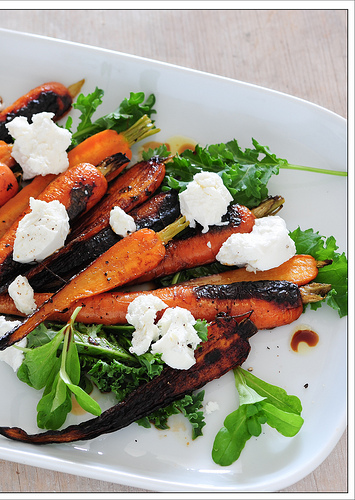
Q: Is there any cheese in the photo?
A: Yes, there is cheese.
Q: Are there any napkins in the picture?
A: No, there are no napkins.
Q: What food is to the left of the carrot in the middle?
A: The food is cheese.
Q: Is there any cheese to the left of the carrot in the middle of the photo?
A: Yes, there is cheese to the left of the carrot.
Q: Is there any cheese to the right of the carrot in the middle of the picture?
A: No, the cheese is to the left of the carrot.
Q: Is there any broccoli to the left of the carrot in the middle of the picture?
A: No, there is cheese to the left of the carrot.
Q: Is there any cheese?
A: Yes, there is cheese.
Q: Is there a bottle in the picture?
A: No, there are no bottles.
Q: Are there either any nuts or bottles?
A: No, there are no bottles or nuts.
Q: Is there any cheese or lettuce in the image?
A: Yes, there is cheese.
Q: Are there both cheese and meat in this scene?
A: No, there is cheese but no meat.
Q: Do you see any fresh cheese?
A: Yes, there is fresh cheese.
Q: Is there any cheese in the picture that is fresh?
A: Yes, there is cheese that is fresh.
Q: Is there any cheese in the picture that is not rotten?
A: Yes, there is fresh cheese.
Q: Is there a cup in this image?
A: No, there are no cups.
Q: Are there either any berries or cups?
A: No, there are no cups or berries.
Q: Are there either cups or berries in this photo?
A: No, there are no cups or berries.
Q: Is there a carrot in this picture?
A: Yes, there is a carrot.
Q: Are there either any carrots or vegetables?
A: Yes, there is a carrot.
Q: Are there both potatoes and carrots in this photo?
A: No, there is a carrot but no potatoes.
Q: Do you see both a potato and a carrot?
A: No, there is a carrot but no potatoes.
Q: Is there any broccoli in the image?
A: No, there is no broccoli.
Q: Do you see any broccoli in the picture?
A: No, there is no broccoli.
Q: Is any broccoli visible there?
A: No, there is no broccoli.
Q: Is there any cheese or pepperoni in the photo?
A: Yes, there is cheese.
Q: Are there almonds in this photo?
A: No, there are no almonds.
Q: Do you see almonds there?
A: No, there are no almonds.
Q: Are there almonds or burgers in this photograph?
A: No, there are no almonds or burgers.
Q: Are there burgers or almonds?
A: No, there are no almonds or burgers.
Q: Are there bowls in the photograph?
A: No, there are no bowls.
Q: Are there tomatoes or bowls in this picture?
A: No, there are no bowls or tomatoes.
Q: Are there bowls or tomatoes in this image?
A: No, there are no bowls or tomatoes.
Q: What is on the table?
A: The herb is on the table.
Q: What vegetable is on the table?
A: The vegetable is a herb.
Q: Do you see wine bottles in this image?
A: No, there are no wine bottles.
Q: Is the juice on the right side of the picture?
A: Yes, the juice is on the right of the image.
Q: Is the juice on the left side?
A: No, the juice is on the right of the image.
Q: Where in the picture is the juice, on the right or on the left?
A: The juice is on the right of the image.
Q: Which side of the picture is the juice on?
A: The juice is on the right of the image.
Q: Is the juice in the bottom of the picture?
A: Yes, the juice is in the bottom of the image.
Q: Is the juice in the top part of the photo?
A: No, the juice is in the bottom of the image.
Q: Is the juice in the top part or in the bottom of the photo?
A: The juice is in the bottom of the image.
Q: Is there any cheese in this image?
A: Yes, there is cheese.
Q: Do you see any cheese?
A: Yes, there is cheese.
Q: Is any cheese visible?
A: Yes, there is cheese.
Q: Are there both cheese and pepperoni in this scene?
A: No, there is cheese but no pepperoni.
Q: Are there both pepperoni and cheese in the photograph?
A: No, there is cheese but no pepperoni.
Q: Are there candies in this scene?
A: No, there are no candies.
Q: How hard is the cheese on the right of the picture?
A: The cheese is soft.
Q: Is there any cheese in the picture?
A: Yes, there is cheese.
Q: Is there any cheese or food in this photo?
A: Yes, there is cheese.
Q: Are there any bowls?
A: No, there are no bowls.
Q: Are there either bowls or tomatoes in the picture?
A: No, there are no bowls or tomatoes.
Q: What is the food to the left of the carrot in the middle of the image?
A: The food is cheese.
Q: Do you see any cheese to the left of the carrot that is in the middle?
A: Yes, there is cheese to the left of the carrot.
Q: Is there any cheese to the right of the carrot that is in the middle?
A: No, the cheese is to the left of the carrot.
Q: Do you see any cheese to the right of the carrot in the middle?
A: No, the cheese is to the left of the carrot.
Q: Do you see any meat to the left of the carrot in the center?
A: No, there is cheese to the left of the carrot.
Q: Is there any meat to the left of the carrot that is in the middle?
A: No, there is cheese to the left of the carrot.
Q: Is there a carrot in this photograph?
A: Yes, there is a carrot.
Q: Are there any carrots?
A: Yes, there is a carrot.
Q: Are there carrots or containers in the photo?
A: Yes, there is a carrot.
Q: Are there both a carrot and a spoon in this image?
A: No, there is a carrot but no spoons.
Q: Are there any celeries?
A: No, there are no celeries.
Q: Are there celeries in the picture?
A: No, there are no celeries.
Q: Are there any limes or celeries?
A: No, there are no celeries or limes.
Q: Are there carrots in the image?
A: Yes, there is a carrot.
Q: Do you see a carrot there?
A: Yes, there is a carrot.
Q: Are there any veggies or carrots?
A: Yes, there is a carrot.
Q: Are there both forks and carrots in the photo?
A: No, there is a carrot but no forks.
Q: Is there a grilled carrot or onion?
A: Yes, there is a grilled carrot.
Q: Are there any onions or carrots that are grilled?
A: Yes, the carrot is grilled.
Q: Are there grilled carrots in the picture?
A: Yes, there is a grilled carrot.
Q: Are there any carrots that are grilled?
A: Yes, there is a carrot that is grilled.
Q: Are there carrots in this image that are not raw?
A: Yes, there is a grilled carrot.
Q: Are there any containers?
A: No, there are no containers.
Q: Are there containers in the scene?
A: No, there are no containers.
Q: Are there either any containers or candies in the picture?
A: No, there are no containers or candies.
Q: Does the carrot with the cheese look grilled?
A: Yes, the carrot is grilled.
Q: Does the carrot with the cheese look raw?
A: No, the carrot is grilled.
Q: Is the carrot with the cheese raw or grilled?
A: The carrot is grilled.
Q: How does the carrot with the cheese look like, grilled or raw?
A: The carrot is grilled.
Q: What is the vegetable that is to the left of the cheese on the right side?
A: The vegetable is a carrot.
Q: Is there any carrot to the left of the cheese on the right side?
A: Yes, there is a carrot to the left of the cheese.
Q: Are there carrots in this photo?
A: Yes, there is a carrot.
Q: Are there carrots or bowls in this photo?
A: Yes, there is a carrot.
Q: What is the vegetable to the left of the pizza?
A: The vegetable is a carrot.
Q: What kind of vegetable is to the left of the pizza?
A: The vegetable is a carrot.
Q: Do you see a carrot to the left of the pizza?
A: Yes, there is a carrot to the left of the pizza.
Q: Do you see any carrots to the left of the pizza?
A: Yes, there is a carrot to the left of the pizza.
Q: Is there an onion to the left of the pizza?
A: No, there is a carrot to the left of the pizza.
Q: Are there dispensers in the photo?
A: No, there are no dispensers.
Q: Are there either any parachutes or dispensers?
A: No, there are no dispensers or parachutes.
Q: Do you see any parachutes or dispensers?
A: No, there are no dispensers or parachutes.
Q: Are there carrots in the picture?
A: Yes, there are carrots.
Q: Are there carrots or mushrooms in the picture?
A: Yes, there are carrots.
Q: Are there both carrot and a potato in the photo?
A: No, there are carrots but no potatoes.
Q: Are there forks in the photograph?
A: No, there are no forks.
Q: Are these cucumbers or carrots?
A: These are carrots.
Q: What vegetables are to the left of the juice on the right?
A: The vegetables are carrots.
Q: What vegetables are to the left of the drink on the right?
A: The vegetables are carrots.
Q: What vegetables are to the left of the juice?
A: The vegetables are carrots.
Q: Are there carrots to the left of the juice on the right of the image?
A: Yes, there are carrots to the left of the juice.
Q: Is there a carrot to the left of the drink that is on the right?
A: Yes, there are carrots to the left of the juice.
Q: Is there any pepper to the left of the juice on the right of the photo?
A: No, there are carrots to the left of the juice.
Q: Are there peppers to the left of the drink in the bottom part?
A: No, there are carrots to the left of the juice.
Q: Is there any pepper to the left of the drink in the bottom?
A: No, there are carrots to the left of the juice.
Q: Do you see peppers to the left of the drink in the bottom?
A: No, there are carrots to the left of the juice.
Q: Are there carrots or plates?
A: Yes, there is a carrot.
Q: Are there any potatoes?
A: No, there are no potatoes.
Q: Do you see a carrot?
A: Yes, there is a carrot.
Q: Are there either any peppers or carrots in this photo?
A: Yes, there is a carrot.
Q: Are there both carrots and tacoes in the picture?
A: No, there is a carrot but no tacoes.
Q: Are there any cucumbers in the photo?
A: No, there are no cucumbers.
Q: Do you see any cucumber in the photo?
A: No, there are no cucumbers.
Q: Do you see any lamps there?
A: No, there are no lamps.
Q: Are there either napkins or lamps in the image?
A: No, there are no lamps or napkins.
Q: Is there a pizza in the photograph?
A: Yes, there is a pizza.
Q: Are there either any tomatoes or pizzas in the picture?
A: Yes, there is a pizza.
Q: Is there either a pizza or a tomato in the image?
A: Yes, there is a pizza.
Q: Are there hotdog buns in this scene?
A: No, there are no hotdog buns.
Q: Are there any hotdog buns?
A: No, there are no hotdog buns.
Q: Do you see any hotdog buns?
A: No, there are no hotdog buns.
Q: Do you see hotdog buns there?
A: No, there are no hotdog buns.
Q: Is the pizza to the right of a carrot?
A: Yes, the pizza is to the right of a carrot.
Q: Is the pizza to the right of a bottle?
A: No, the pizza is to the right of a carrot.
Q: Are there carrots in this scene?
A: Yes, there is a carrot.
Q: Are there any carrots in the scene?
A: Yes, there is a carrot.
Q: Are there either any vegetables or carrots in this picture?
A: Yes, there is a carrot.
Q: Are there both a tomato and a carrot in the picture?
A: No, there is a carrot but no tomatoes.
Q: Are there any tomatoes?
A: No, there are no tomatoes.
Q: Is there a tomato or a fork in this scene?
A: No, there are no tomatoes or forks.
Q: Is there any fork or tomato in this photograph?
A: No, there are no tomatoes or forks.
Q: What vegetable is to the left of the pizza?
A: The vegetable is a carrot.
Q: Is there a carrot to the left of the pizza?
A: Yes, there is a carrot to the left of the pizza.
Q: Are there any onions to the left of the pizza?
A: No, there is a carrot to the left of the pizza.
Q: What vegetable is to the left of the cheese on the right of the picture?
A: The vegetable is a carrot.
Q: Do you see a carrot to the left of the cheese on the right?
A: Yes, there is a carrot to the left of the cheese.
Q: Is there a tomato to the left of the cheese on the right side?
A: No, there is a carrot to the left of the cheese.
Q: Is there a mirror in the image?
A: No, there are no mirrors.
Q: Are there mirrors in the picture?
A: No, there are no mirrors.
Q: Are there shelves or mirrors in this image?
A: No, there are no mirrors or shelves.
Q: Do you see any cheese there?
A: Yes, there is cheese.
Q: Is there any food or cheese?
A: Yes, there is cheese.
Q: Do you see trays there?
A: No, there are no trays.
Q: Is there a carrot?
A: Yes, there is a carrot.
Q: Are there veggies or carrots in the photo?
A: Yes, there is a carrot.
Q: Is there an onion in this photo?
A: No, there are no onions.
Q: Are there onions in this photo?
A: No, there are no onions.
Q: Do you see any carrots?
A: Yes, there is a carrot.